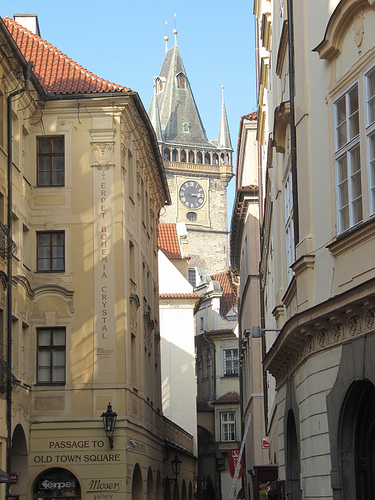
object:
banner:
[228, 447, 243, 480]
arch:
[129, 461, 144, 500]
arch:
[31, 463, 82, 498]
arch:
[146, 465, 155, 499]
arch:
[156, 467, 162, 497]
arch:
[163, 475, 172, 498]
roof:
[3, 15, 140, 95]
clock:
[179, 180, 206, 210]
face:
[179, 180, 204, 209]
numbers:
[189, 180, 194, 187]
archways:
[160, 142, 232, 176]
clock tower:
[134, 11, 232, 270]